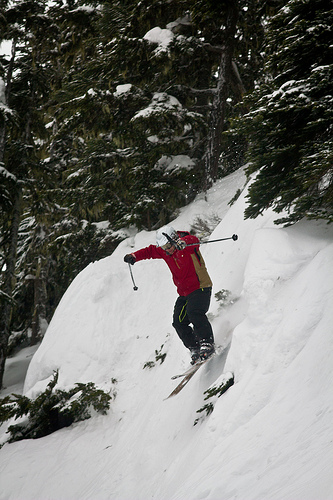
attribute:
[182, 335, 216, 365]
boots — black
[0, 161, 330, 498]
snow — White 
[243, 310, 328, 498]
snow — white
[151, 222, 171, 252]
helmet — white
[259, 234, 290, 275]
snow — white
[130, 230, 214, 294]
jacket — red 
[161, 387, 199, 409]
snow — white